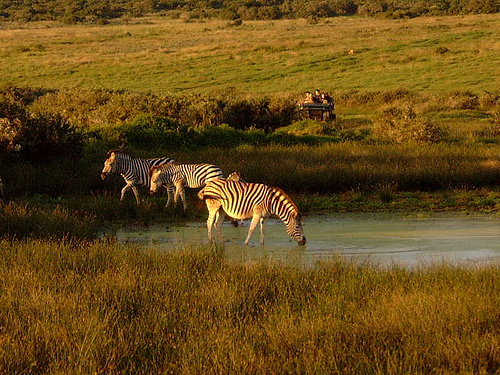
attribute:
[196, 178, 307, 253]
zebra — drinking, striped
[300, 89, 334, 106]
people — on safari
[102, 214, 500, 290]
water — small, rippled, curved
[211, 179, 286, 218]
stripes — black, white, vertical, horizontal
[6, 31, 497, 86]
grass — brown, green, tall, yellow, dead, thin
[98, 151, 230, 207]
zebra — walking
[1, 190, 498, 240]
grass — tall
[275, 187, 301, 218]
hair — black, brown, long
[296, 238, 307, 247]
nose — black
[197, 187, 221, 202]
tail — curved